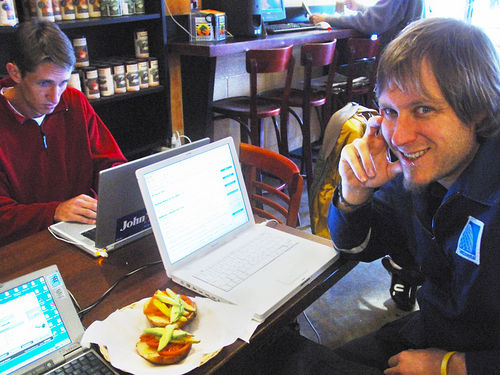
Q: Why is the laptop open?
A: In use.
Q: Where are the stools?
A: Bar.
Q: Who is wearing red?
A: Man looking at screen.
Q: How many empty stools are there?
A: 3.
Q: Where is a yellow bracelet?
A: Smiling man's wrist.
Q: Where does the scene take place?
A: In a restaurant.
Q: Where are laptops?
A: On a table.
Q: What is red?
A: Bar stools.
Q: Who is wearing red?
A: Man on left.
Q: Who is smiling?
A: Man on right.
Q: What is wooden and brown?
A: Table.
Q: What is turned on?
A: Computer screens.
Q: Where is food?
A: On a plate.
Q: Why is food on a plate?
A: To be eaten.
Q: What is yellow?
A: Man's bracelet.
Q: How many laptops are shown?
A: 3.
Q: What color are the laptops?
A: Silver.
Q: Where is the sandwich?
A: Beside the laptop.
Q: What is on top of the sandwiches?
A: Pickles.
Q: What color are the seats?
A: Red.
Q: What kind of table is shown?
A: Wooden.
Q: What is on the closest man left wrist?
A: Yellow band.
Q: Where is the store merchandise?
A: Shelves.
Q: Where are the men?
A: In a coffee shop.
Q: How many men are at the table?
A: Two.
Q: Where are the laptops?
A: On the table.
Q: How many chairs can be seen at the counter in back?
A: Three.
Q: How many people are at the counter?
A: One.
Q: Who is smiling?
A: The man on the right.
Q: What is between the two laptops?
A: An open-faced sandwich.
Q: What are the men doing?
A: Working on laptops.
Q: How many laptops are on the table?
A: Three.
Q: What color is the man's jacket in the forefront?
A: Black.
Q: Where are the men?
A: In a cafe.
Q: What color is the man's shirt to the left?
A: Red.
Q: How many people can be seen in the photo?
A: Three.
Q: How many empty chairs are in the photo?
A: Four.